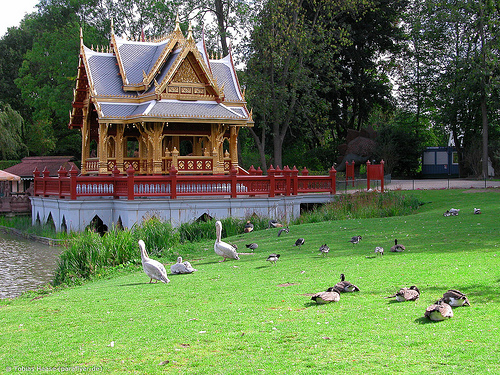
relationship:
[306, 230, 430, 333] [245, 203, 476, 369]
duck on grass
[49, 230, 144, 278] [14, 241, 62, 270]
plants on edge of water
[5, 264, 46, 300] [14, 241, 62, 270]
reeds next to water